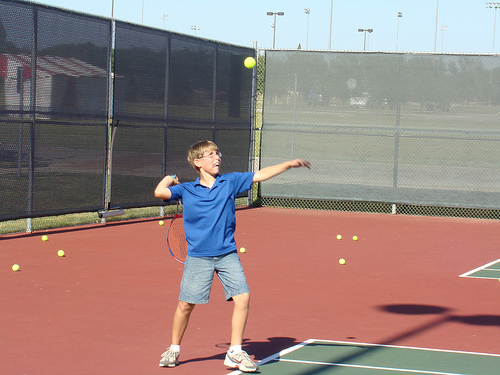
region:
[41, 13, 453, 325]
this is a boy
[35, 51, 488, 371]
the boy is playing tennis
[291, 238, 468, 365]
the court is made of clay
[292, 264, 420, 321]
the clay is red here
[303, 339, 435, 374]
the clay is green here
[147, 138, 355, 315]
the boy is wearing blue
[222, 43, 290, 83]
this is a tennis ball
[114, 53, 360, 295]
the boy is serving a tennis ball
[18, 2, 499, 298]
the netting is black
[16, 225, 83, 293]
these are three tennis balls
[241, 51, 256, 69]
A yellow tennis ball in the air.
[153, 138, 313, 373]
A boy wearing a blue shirt.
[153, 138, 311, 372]
A boy wearing blue jean shorts.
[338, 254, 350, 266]
A tennis ball on the ground.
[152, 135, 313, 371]
A young boy playing tennis.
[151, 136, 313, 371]
A young boy wearing glasses.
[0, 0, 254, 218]
One side of a fence.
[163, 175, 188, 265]
A red and blue tennis racket.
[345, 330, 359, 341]
The shadow of a tennis ball.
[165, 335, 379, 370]
The shadow of a young boy.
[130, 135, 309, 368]
a boy holding a tennis racket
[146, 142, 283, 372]
a boy preparing to swing a tennis racket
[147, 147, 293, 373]
a boy wearing a blue shirt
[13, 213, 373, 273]
several yellow tennis balls on the ground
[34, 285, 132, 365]
red surface of the tennis court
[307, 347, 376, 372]
green surface of the tennis court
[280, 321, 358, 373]
white lines painted on the tennis court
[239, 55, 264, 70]
a yellow tennis ball in midair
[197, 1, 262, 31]
clear blue skies over the tennis court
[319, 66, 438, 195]
black screen on the fence surrounding the tennis court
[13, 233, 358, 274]
yellow balls on a red floor of a tennis court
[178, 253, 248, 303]
boy wearing blue jean shorts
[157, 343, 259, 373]
boy wearing white sneakers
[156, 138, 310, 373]
boy about to hit a ball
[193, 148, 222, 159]
boy wearing glasses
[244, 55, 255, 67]
a yellow ball flying in the air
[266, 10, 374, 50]
flooding lights outside a tennis court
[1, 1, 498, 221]
green tarp over a metal fence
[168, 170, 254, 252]
boy wearing a blue shirt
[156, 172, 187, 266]
boy holding a tennis racket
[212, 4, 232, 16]
this is the sky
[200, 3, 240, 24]
the sky is blue in color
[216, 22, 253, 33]
the sky has clouds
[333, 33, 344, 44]
the clouds are white in color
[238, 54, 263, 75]
the ball is in the air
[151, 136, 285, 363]
this is a boy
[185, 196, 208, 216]
the t-shirt is blue in color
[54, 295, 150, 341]
this is the tennis pitch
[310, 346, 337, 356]
the floor is green in color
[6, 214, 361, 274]
the balls are on the ground